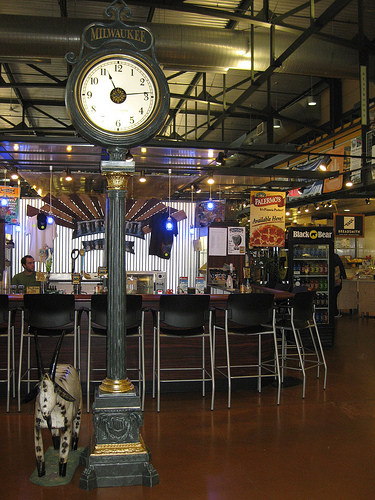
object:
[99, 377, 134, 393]
metal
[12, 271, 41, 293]
shirt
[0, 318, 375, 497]
floors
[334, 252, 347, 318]
person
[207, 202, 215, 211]
light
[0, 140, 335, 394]
bar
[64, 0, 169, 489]
clock post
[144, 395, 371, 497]
brown ground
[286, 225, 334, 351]
cooler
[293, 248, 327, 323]
drinks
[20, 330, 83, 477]
goat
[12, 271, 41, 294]
green shirt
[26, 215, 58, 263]
shirt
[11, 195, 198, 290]
wall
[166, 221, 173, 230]
light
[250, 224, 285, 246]
pizza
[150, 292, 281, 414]
stools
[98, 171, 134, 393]
lamp post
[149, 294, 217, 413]
chair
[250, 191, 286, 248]
sign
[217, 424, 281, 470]
tiled floor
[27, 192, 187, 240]
brown logo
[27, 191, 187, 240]
tan sign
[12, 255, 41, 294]
man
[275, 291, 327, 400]
chair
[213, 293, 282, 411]
chair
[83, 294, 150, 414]
chair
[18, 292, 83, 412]
chair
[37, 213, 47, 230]
cap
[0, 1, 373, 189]
beams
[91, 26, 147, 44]
lettering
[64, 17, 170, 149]
clock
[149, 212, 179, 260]
shirt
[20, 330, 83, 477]
goat sculpture